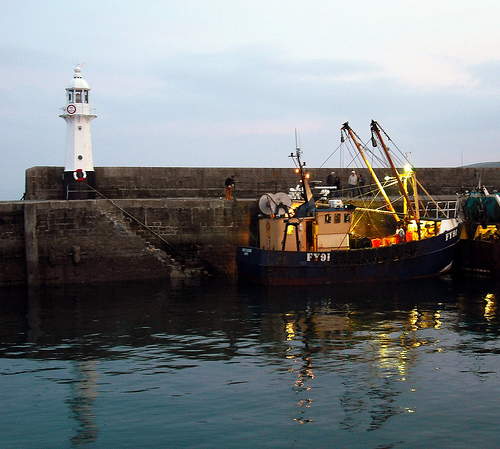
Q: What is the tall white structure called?
A: Lighthouse.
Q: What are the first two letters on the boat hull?
A: FY.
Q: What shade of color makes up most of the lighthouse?
A: White.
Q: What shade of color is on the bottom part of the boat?
A: Black.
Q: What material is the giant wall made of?
A: Concrete.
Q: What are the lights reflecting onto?
A: Water.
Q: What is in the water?
A: A boat.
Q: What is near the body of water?
A: A crane.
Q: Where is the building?
A: On the pier.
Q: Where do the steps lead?
A: To the lighthouse.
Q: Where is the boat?
A: In a body of water.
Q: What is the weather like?
A: Cloudy.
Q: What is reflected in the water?
A: Lights.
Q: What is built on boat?
A: A small room.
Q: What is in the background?
A: Lighthouse.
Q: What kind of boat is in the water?
A: Fishing boat.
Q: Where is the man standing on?
A: Dock.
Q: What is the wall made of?
A: Concrete.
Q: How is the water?
A: Calm.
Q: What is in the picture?
A: A boat.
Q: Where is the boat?
A: On water.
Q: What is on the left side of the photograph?
A: A tower.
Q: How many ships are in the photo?
A: One.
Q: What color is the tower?
A: White.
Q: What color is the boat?
A: Black.